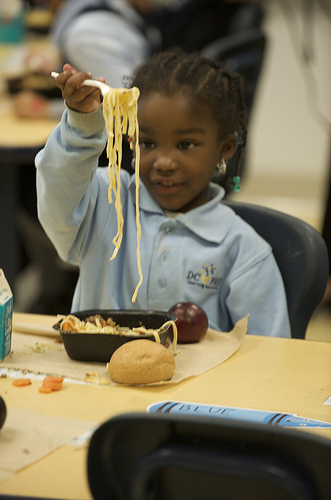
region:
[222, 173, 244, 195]
Green beads in girl's hair.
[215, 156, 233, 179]
Small earrings on girl's ear.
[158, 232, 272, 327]
Girl wearing blue shirt.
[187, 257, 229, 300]
Black lettering on girl's shirt.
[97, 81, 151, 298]
Girl eating noodles at table.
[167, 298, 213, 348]
Purple plum sitting on table.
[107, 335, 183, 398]
Brown biscuit sitting on table.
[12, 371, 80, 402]
Pieces of carrot sitting on table.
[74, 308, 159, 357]
Pasta in black container on table.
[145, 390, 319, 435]
Blue crayon sticker on table.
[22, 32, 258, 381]
child eating a school lunch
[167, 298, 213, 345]
red appe on brown napkin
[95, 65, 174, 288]
child lifint noodles with fork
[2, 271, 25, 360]
carton of milk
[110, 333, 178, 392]
bread roll on top of brown napkin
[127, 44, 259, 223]
child with hair in braids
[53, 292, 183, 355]
black plastic container holding food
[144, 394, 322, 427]
blue crayon on table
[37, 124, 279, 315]
girl wearing a blue school uniform shirt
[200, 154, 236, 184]
girl wearing silver earrings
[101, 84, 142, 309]
pasta on a fork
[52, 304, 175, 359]
black plastic bowl with pasta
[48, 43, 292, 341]
girl eating pasta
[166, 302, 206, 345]
dark red apple on napkin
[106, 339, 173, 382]
wheat bun on a napkin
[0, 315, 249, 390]
brown napkin under lunch items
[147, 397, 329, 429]
crayon symbol taped to table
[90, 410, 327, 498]
back of a school chair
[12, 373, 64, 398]
chopped up carrots on the table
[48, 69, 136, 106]
white fork in the girl's hand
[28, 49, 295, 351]
a little girl holding up noodles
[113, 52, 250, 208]
she has braids in her hair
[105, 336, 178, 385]
a bread roll on the table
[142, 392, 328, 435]
a picture of a blue crayon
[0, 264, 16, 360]
a small carton of milk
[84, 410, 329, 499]
the chair by the crayon is black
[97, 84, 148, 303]
the noodles are long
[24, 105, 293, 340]
the sweater is light blue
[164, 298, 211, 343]
a dark red apple on the table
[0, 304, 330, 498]
the table is brown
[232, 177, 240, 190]
Green beads.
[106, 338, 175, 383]
A light brown bread roll.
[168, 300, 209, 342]
A dark red colored apple.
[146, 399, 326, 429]
A picture on the table of a blue crayon.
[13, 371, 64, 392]
Sliced orange carrots.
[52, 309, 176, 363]
A black food container.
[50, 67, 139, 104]
A white plastic fork.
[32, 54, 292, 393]
A young girl about to eat some pasta.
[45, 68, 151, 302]
Pasta noodles on a fork hanging above the bowl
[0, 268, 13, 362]
A blue and white small carton.